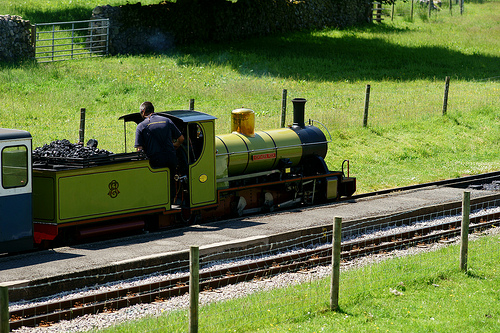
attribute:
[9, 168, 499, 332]
train tracks — metal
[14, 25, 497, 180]
grass — green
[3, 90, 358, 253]
train — small, green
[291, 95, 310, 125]
smoke stack — black, small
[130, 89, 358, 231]
engine — green, small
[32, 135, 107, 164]
coal — black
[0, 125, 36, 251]
car — blue, white, small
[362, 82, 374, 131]
post — wooden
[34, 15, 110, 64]
gate — metal, silver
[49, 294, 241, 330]
gravel — gray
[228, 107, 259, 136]
boiler — gold